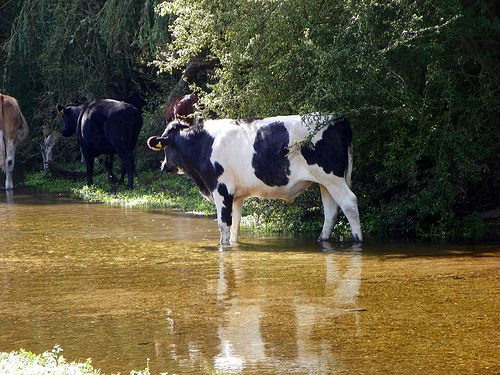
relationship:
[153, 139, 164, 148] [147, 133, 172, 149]
tag on ear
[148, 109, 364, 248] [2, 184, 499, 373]
cow wading in water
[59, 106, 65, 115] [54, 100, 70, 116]
tag on ear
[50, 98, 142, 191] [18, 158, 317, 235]
cow walking on bank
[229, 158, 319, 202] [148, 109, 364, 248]
stomach of a cow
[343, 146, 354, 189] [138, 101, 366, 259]
tail of a cow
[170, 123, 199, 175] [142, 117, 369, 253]
neck of a cow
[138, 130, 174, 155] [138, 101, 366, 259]
ear of a cow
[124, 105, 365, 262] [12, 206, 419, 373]
bull in water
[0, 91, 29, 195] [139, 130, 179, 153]
bull has horns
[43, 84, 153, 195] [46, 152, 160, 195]
bull standing on grass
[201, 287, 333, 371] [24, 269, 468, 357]
reflection in water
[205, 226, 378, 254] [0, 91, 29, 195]
feet of bull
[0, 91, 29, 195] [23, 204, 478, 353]
bull in water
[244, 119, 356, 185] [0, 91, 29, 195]
spots on bull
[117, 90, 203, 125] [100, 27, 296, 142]
bull in bushes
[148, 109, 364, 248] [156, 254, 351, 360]
cow in water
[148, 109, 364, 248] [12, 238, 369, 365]
cow in water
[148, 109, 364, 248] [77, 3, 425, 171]
cow with trees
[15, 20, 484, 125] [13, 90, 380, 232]
trees with cows